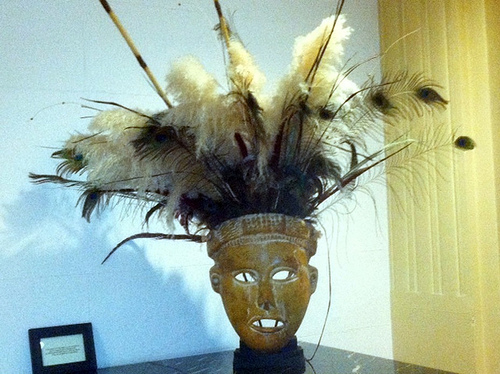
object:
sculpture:
[206, 213, 322, 352]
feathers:
[131, 121, 221, 195]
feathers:
[310, 131, 482, 219]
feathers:
[325, 72, 449, 161]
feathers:
[225, 74, 272, 157]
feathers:
[77, 186, 106, 224]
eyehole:
[232, 267, 259, 285]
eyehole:
[269, 265, 299, 281]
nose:
[256, 278, 276, 311]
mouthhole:
[251, 315, 285, 331]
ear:
[207, 266, 223, 295]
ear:
[306, 267, 319, 294]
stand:
[231, 340, 304, 372]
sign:
[28, 323, 98, 373]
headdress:
[27, 2, 475, 267]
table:
[94, 351, 230, 374]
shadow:
[2, 237, 223, 374]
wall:
[0, 2, 161, 374]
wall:
[377, 2, 499, 371]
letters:
[45, 347, 81, 357]